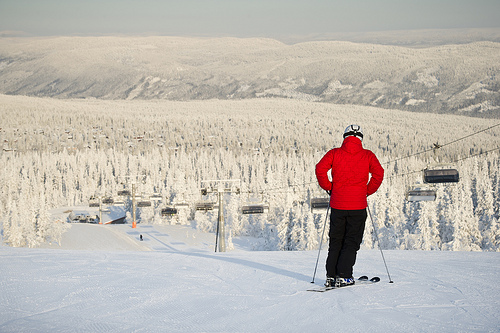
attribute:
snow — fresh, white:
[25, 251, 494, 332]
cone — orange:
[129, 219, 139, 230]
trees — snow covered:
[101, 134, 197, 196]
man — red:
[319, 125, 384, 289]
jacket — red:
[315, 140, 384, 210]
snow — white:
[3, 245, 499, 329]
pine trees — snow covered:
[3, 95, 497, 250]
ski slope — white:
[20, 232, 472, 319]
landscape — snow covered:
[4, 38, 493, 248]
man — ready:
[308, 119, 383, 279]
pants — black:
[325, 209, 367, 280]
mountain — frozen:
[80, 23, 471, 138]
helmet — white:
[338, 118, 366, 138]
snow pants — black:
[326, 208, 368, 280]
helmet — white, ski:
[339, 122, 366, 139]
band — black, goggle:
[343, 129, 365, 136]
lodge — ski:
[65, 198, 135, 239]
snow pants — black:
[323, 202, 363, 278]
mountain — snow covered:
[5, 31, 484, 123]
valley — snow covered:
[2, 96, 485, 246]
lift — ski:
[93, 120, 497, 252]